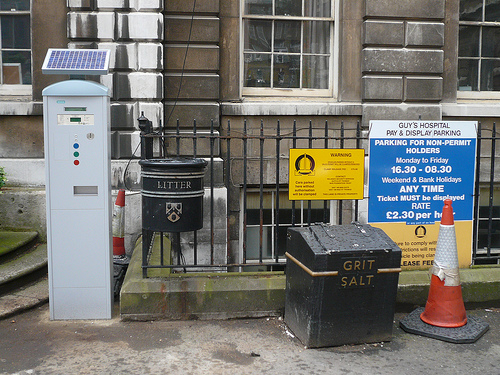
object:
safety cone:
[398, 197, 495, 346]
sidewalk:
[2, 297, 500, 373]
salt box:
[281, 220, 401, 348]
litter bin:
[137, 155, 209, 232]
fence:
[136, 114, 499, 279]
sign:
[366, 118, 479, 267]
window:
[240, 0, 338, 100]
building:
[0, 1, 499, 277]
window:
[455, 0, 500, 101]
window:
[238, 185, 337, 273]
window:
[474, 183, 499, 265]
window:
[0, 0, 35, 97]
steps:
[0, 276, 48, 319]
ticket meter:
[41, 47, 111, 322]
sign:
[289, 147, 364, 201]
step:
[0, 230, 39, 261]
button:
[72, 143, 79, 149]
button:
[74, 159, 81, 165]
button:
[73, 151, 80, 157]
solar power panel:
[40, 47, 111, 77]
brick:
[406, 21, 444, 45]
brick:
[360, 20, 406, 48]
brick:
[361, 47, 445, 75]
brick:
[361, 75, 404, 102]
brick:
[404, 74, 444, 103]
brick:
[363, 0, 446, 21]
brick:
[362, 101, 442, 126]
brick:
[177, 228, 227, 266]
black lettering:
[318, 153, 358, 196]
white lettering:
[374, 139, 471, 220]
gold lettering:
[340, 260, 376, 287]